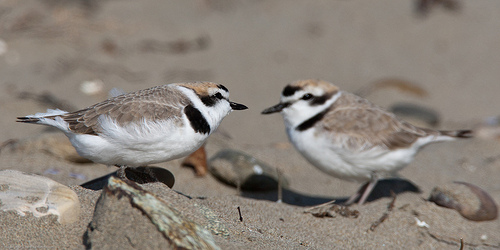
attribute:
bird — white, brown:
[266, 79, 441, 192]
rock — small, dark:
[79, 79, 430, 238]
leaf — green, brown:
[117, 185, 199, 245]